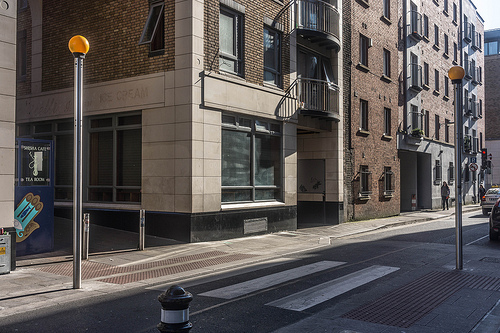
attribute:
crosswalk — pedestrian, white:
[135, 256, 446, 316]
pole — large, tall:
[73, 57, 82, 289]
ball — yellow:
[69, 35, 91, 57]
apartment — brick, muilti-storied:
[19, 0, 484, 243]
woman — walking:
[440, 180, 450, 212]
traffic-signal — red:
[482, 150, 488, 155]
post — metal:
[453, 82, 464, 270]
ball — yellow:
[449, 67, 464, 80]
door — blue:
[17, 137, 54, 256]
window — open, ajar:
[139, 2, 164, 45]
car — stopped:
[482, 187, 499, 214]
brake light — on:
[480, 195, 486, 201]